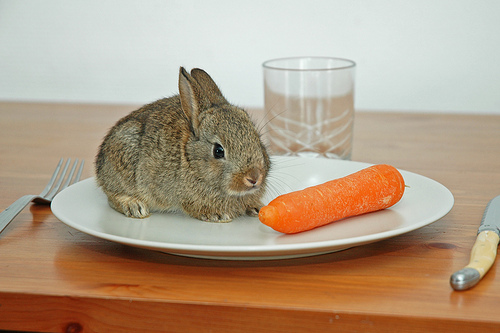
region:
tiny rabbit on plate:
[97, 71, 267, 218]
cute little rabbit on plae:
[94, 68, 265, 218]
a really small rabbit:
[98, 73, 270, 220]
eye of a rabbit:
[211, 139, 228, 156]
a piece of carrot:
[274, 157, 396, 235]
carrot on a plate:
[258, 158, 402, 240]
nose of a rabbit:
[240, 168, 266, 185]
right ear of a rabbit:
[173, 72, 204, 132]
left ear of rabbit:
[195, 64, 228, 106]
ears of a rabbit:
[174, 64, 227, 120]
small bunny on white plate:
[119, 94, 277, 199]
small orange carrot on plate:
[259, 147, 419, 239]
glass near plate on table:
[244, 47, 375, 162]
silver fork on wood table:
[12, 153, 102, 303]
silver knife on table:
[449, 173, 499, 288]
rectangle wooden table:
[14, 88, 496, 298]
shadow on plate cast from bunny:
[67, 166, 425, 247]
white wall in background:
[20, 5, 464, 118]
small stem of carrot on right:
[389, 165, 435, 207]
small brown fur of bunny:
[141, 134, 208, 188]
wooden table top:
[1, 97, 497, 327]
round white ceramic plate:
[50, 152, 450, 259]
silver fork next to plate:
[0, 155, 85, 230]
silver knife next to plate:
[450, 195, 495, 287]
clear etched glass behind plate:
[262, 52, 352, 157]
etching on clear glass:
[262, 107, 352, 157]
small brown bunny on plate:
[90, 65, 299, 225]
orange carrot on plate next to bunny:
[255, 165, 402, 235]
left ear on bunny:
[175, 65, 205, 131]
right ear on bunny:
[190, 65, 226, 103]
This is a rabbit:
[94, 58, 275, 235]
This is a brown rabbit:
[91, 52, 272, 222]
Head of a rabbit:
[187, 95, 272, 198]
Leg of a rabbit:
[109, 165, 160, 245]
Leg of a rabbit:
[181, 176, 236, 233]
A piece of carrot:
[254, 143, 416, 239]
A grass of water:
[250, 9, 361, 177]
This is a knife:
[438, 148, 499, 323]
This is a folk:
[1, 112, 79, 276]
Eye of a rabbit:
[206, 131, 236, 164]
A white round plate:
[49, 151, 456, 264]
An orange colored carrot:
[256, 161, 405, 236]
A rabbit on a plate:
[46, 64, 456, 264]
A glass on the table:
[249, 49, 367, 162]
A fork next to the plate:
[1, 155, 86, 254]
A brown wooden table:
[1, 96, 498, 330]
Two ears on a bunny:
[175, 64, 226, 114]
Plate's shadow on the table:
[54, 226, 454, 311]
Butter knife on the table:
[446, 193, 498, 293]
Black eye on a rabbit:
[201, 131, 232, 171]